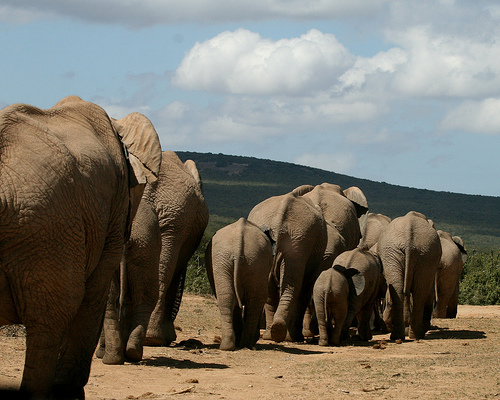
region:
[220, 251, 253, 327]
tail of an elephant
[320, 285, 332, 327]
tail of an elephant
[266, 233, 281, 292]
tail of an elephant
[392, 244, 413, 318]
tail of an elephant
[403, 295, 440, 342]
leg of an elephant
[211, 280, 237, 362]
leg of an elephant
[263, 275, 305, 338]
leg of an elephant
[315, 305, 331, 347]
leg of an elephant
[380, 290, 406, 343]
leg of an elephant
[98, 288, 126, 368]
leg of an elephant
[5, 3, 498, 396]
Exterior shot, taken on cloudy day.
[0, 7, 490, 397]
Depiction of natural landscape, with verdant and dry areas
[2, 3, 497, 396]
Wild animals seen in their natural surroundings.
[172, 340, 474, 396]
Medium brown, dirt terrain, showing clods and shadow.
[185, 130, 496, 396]
Dirt area, overlooks verdant, forested region and green mountains, beyond.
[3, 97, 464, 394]
Elephant herd, migrating towards greener areas.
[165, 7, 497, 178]
Pale, blue sky with large, white clouds.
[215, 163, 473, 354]
Close-packed cluster of elephants, with adults and babies.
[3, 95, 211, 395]
Three, large elephants moving apart from the close-packed bunch ahead.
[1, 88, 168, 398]
Very large, standing elephant at the rear of the herd.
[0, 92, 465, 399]
a group of elephants walking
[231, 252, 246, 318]
an elephants tail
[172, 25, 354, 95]
a white cloud fluffy cloud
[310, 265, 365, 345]
a grey baby elephant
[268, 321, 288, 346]
the bottom of an elephants foot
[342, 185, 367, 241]
a grey elephants right ear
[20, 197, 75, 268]
a patch of elephants skin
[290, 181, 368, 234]
an adult elephant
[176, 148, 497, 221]
a green hill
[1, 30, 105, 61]
a patch of blue sky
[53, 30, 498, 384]
elephants walking in groups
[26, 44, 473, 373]
elephants walking on dirt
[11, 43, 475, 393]
elephants walking in a field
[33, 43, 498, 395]
elephants walking on a dirt field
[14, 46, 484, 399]
elephants walking in an area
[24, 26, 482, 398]
elephants walking together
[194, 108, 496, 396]
different size elephants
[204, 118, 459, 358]
different size elephants together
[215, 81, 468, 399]
an area with elephants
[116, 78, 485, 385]
an area with dirt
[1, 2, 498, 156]
white clouds in the blue sky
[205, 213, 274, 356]
baby elephant walking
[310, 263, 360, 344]
tiny elephant in the back of the group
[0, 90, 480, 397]
a group of elephants walking together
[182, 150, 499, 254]
hill of trees in the background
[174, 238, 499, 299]
bushes in front of the elephants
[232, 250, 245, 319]
tail of an elephant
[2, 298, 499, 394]
rocks and dirt on the ground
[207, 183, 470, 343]
a family of elephants walking together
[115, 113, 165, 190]
elephant ear